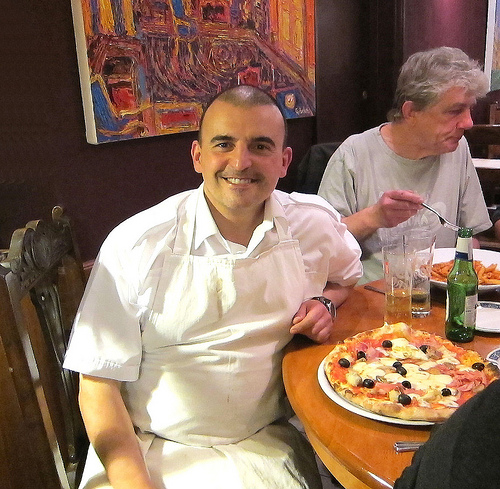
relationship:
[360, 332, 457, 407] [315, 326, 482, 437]
pizza on plate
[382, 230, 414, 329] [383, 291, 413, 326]
glass with beer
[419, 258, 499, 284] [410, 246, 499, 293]
pasta in plate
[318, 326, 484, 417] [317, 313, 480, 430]
plate of pizza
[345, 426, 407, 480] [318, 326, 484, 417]
table with plate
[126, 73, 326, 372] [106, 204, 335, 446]
man in an apron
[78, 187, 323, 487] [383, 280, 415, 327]
apron of beer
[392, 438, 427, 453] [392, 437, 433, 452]
handle of service utensil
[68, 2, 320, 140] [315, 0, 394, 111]
painting on wall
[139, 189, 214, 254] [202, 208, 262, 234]
strings around neck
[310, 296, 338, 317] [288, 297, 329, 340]
watch on hand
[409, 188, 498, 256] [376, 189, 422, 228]
spoon in man's hand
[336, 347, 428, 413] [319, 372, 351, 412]
pizza pie on plate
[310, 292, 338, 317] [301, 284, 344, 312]
watch on a wrist